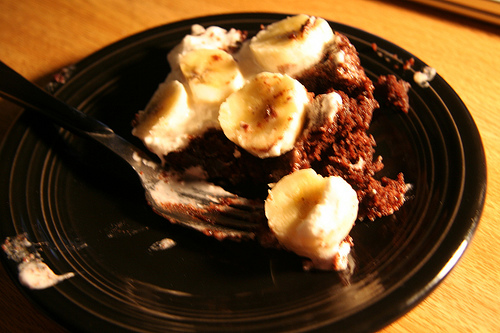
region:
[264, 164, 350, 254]
A slice of banana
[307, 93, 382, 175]
chocolate cake crumbs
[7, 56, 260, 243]
a fork on a plate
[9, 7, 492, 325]
a black round plate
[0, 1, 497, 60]
a wood grain table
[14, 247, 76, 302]
icing on a plate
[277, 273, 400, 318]
a reflection on the plate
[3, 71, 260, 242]
icing an cake on a fork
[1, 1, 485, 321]
bananas and cake on a plate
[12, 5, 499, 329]
bananas and cake on a black plate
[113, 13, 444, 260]
food on the plate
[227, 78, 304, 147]
piece of white food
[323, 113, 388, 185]
brown food on the plate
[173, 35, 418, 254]
many pieces of food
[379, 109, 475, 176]
black plate under food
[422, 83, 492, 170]
edge of the plate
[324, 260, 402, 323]
light hitting the plate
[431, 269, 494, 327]
table under the plate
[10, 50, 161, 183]
handle of the fork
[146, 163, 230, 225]
white stuff on the spoon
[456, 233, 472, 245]
part of a plate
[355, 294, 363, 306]
edge of a plate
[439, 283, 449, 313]
part of a table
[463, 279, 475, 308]
edge of a table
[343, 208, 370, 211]
part of a food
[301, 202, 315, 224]
part of a potato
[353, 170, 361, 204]
part of a meat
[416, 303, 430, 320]
edge of a table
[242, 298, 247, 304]
edge of a plate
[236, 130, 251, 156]
edge of a potato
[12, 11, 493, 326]
food on a black dish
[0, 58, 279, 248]
a spoon on a black dish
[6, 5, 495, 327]
black dish is plastic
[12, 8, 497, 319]
black dish is over a wood table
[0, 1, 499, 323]
wood table is color brown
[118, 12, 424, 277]
bananas over a cake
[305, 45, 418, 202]
chocolate cake on black dish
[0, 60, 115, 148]
handle of spoon in black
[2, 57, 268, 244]
the spoon is dirty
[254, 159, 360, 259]
a slice of banana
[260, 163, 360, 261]
Yellow food on plate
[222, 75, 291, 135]
Yellow food on plate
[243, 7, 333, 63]
Yellow food on plate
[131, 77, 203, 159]
Yellow food on plate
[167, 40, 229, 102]
Yellow food on plate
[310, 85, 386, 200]
Yellow food on plate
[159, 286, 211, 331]
Black ripples on plate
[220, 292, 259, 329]
Black ripples on plate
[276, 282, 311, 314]
Black ripples on plate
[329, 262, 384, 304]
Black ripples on plate